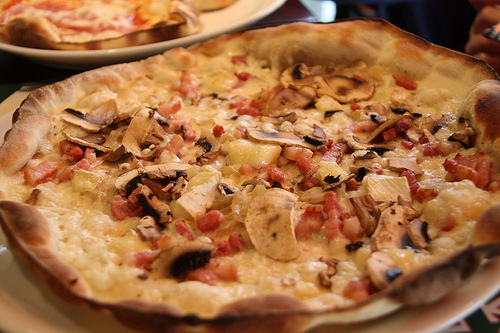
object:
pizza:
[0, 18, 499, 314]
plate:
[4, 20, 499, 332]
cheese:
[157, 60, 262, 111]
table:
[0, 0, 499, 333]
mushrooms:
[79, 133, 108, 146]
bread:
[14, 82, 62, 129]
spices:
[232, 54, 261, 96]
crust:
[168, 32, 481, 74]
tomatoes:
[244, 188, 303, 262]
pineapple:
[227, 138, 282, 167]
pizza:
[0, 4, 208, 49]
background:
[12, 2, 496, 68]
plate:
[4, 6, 296, 64]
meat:
[141, 177, 171, 200]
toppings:
[123, 122, 437, 233]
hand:
[461, 12, 499, 66]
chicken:
[359, 174, 413, 206]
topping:
[35, 159, 76, 191]